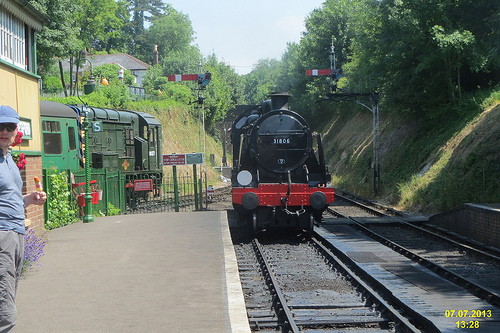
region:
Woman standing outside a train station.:
[0, 105, 30, 330]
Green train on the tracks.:
[42, 104, 164, 213]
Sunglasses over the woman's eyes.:
[0, 122, 20, 134]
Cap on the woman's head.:
[1, 105, 21, 124]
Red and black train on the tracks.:
[227, 89, 337, 246]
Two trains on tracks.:
[39, 90, 336, 239]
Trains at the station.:
[41, 87, 336, 247]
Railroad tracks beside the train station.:
[250, 240, 435, 326]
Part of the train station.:
[0, 46, 45, 238]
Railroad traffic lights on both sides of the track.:
[164, 59, 386, 196]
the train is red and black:
[243, 106, 327, 328]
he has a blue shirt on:
[3, 196, 68, 271]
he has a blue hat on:
[1, 98, 31, 139]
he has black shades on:
[1, 125, 31, 142]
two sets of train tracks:
[252, 241, 495, 319]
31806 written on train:
[273, 129, 324, 183]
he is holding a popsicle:
[1, 180, 73, 223]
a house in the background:
[100, 47, 196, 132]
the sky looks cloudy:
[219, 46, 256, 63]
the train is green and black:
[50, 96, 170, 207]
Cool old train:
[226, 90, 336, 247]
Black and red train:
[227, 90, 337, 245]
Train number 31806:
[230, 91, 335, 245]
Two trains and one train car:
[41, 87, 337, 242]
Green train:
[41, 97, 163, 224]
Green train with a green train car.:
[39, 97, 163, 226]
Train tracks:
[245, 240, 499, 332]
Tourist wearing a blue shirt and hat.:
[0, 102, 44, 331]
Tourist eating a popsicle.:
[0, 103, 49, 331]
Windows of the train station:
[0, 0, 39, 82]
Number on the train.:
[266, 128, 308, 160]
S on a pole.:
[77, 107, 109, 137]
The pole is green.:
[76, 128, 108, 226]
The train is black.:
[229, 97, 326, 181]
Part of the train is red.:
[222, 180, 342, 215]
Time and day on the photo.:
[418, 289, 498, 330]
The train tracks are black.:
[239, 247, 426, 332]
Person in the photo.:
[0, 95, 51, 330]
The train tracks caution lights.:
[158, 55, 223, 136]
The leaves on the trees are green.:
[356, 32, 494, 91]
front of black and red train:
[238, 88, 328, 233]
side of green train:
[52, 108, 164, 212]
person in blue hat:
[0, 97, 35, 179]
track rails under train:
[255, 232, 334, 271]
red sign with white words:
[158, 150, 189, 170]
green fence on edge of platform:
[103, 167, 188, 214]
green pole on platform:
[78, 110, 95, 224]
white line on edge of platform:
[220, 239, 239, 297]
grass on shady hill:
[389, 122, 435, 156]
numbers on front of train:
[266, 132, 297, 148]